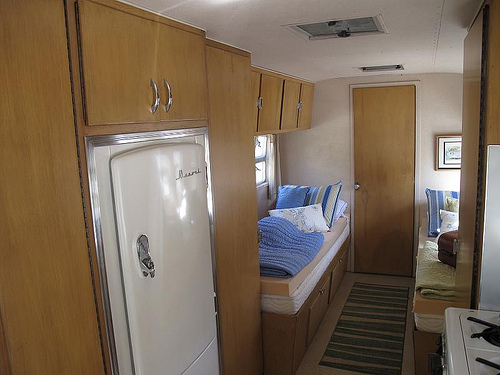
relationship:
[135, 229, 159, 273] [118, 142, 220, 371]
handle to a refrigerator door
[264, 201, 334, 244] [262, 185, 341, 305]
pillow on a bed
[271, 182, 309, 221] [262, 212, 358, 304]
pillow on a bed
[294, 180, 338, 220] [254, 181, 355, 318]
pillow on a bed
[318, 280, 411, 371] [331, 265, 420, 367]
floor mat on a floor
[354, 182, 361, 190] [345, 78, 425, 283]
door handle to a door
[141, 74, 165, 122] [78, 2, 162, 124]
handle to cabinet door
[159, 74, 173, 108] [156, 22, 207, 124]
handle to cabinet door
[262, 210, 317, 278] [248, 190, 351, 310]
blanket on a bed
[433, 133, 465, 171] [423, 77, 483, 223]
framed painting on a wall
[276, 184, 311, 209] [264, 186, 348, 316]
pillow on a bed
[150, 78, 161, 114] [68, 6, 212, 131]
handle on cabinets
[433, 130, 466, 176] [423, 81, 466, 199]
frame on a wall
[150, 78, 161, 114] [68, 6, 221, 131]
handle are on cabinets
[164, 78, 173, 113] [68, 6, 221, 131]
handle are on cabinets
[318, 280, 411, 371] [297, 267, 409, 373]
floor mat on floor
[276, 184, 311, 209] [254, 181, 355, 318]
pillow are on bed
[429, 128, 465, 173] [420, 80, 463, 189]
framed painting on wall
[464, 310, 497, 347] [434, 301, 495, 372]
burner on stove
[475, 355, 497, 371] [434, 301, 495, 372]
burner on stove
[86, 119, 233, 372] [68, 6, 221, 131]
fridge under cabinets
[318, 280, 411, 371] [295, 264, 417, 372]
floor mat on floor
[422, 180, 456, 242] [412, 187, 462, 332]
pillows are on bed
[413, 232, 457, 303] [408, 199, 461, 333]
blanket on bed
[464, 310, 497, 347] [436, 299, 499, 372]
burner on stove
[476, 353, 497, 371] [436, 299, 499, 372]
burner on stove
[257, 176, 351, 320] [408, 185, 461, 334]
bed across from bed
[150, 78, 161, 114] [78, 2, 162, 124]
handle on cabinet door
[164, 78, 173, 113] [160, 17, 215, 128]
handle on door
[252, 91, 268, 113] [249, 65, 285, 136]
hendge on door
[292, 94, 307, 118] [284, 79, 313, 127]
hendge on door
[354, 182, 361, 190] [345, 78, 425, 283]
door handle on door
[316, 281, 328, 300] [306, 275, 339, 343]
hendge on door